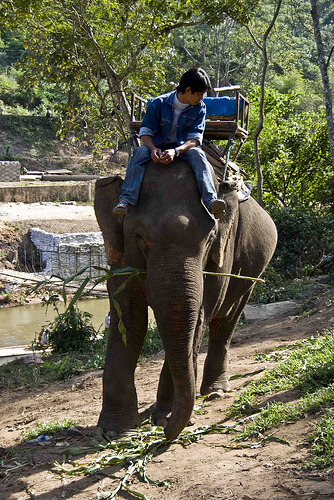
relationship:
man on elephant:
[113, 68, 227, 221] [94, 139, 278, 440]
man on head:
[113, 68, 227, 221] [123, 157, 218, 239]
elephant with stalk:
[94, 139, 278, 440] [25, 265, 266, 346]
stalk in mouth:
[25, 265, 266, 346] [145, 267, 205, 280]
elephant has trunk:
[94, 139, 278, 440] [144, 254, 204, 441]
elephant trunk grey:
[94, 139, 278, 440] [161, 276, 173, 305]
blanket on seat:
[203, 94, 244, 117] [128, 94, 251, 139]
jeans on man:
[119, 145, 219, 210] [113, 68, 227, 221]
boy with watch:
[113, 68, 227, 221] [174, 148, 179, 160]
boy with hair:
[113, 68, 227, 221] [178, 68, 212, 95]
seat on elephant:
[129, 83, 250, 196] [94, 139, 278, 440]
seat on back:
[129, 83, 250, 196] [200, 142, 243, 189]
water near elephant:
[3, 298, 108, 348] [94, 139, 278, 440]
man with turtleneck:
[113, 68, 227, 221] [172, 92, 191, 115]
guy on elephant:
[113, 68, 227, 221] [94, 139, 278, 440]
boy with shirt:
[113, 68, 227, 221] [167, 94, 191, 145]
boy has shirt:
[113, 68, 227, 221] [167, 94, 191, 145]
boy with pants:
[113, 68, 227, 221] [119, 145, 219, 210]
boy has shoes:
[113, 68, 227, 221] [114, 200, 228, 221]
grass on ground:
[239, 328, 332, 463] [2, 374, 329, 499]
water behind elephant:
[3, 298, 108, 348] [94, 139, 278, 440]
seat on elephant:
[128, 94, 251, 139] [94, 139, 278, 440]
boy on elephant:
[113, 68, 227, 221] [94, 139, 278, 440]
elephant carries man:
[94, 139, 278, 440] [113, 68, 227, 221]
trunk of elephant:
[144, 254, 204, 441] [94, 139, 278, 440]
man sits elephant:
[113, 68, 227, 221] [94, 139, 278, 440]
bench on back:
[128, 94, 251, 139] [200, 142, 243, 189]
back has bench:
[200, 142, 243, 189] [128, 94, 251, 139]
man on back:
[113, 68, 227, 221] [200, 142, 243, 189]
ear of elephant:
[93, 177, 125, 267] [94, 139, 278, 440]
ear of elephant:
[210, 183, 239, 271] [94, 139, 278, 440]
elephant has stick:
[94, 139, 278, 440] [28, 270, 261, 288]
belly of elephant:
[202, 269, 244, 323] [94, 139, 278, 440]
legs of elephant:
[98, 277, 204, 433] [94, 139, 278, 440]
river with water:
[3, 298, 108, 348] [11, 269, 185, 378]